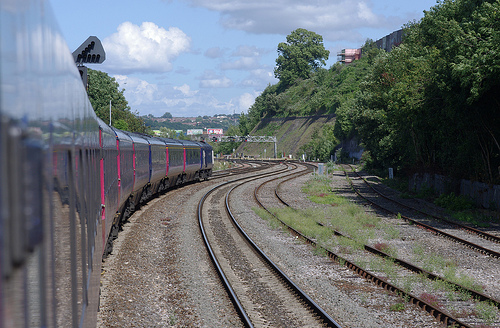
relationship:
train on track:
[3, 2, 211, 324] [93, 157, 254, 327]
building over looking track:
[337, 48, 359, 67] [330, 158, 499, 255]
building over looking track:
[337, 48, 359, 67] [254, 151, 494, 326]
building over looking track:
[337, 48, 359, 67] [196, 158, 335, 325]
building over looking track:
[337, 48, 359, 67] [93, 157, 254, 327]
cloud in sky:
[103, 18, 186, 72] [48, 1, 444, 117]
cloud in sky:
[200, 0, 387, 38] [48, 1, 444, 117]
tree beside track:
[273, 28, 328, 84] [93, 157, 254, 327]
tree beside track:
[346, 50, 412, 166] [93, 157, 254, 327]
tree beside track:
[396, 58, 457, 181] [93, 157, 254, 327]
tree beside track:
[455, 26, 499, 190] [93, 157, 254, 327]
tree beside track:
[455, 26, 499, 190] [330, 158, 499, 255]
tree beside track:
[455, 26, 499, 190] [254, 151, 494, 326]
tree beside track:
[455, 26, 499, 190] [196, 158, 335, 325]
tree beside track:
[396, 58, 457, 181] [330, 158, 499, 255]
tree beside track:
[396, 58, 457, 181] [254, 151, 494, 326]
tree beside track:
[346, 50, 412, 166] [330, 158, 499, 255]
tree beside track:
[346, 50, 412, 166] [254, 151, 494, 326]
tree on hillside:
[273, 28, 328, 84] [234, 38, 497, 205]